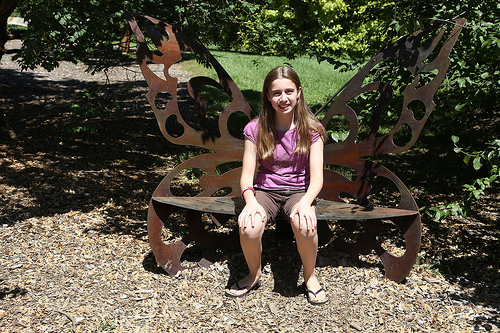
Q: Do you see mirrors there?
A: No, there are no mirrors.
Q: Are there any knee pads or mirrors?
A: No, there are no mirrors or knee pads.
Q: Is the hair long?
A: Yes, the hair is long.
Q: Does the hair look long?
A: Yes, the hair is long.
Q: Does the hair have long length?
A: Yes, the hair is long.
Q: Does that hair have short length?
A: No, the hair is long.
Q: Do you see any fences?
A: No, there are no fences.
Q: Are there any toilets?
A: No, there are no toilets.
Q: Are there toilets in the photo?
A: No, there are no toilets.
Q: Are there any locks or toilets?
A: No, there are no toilets or locks.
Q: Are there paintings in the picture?
A: No, there are no paintings.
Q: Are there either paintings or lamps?
A: No, there are no paintings or lamps.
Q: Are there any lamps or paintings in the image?
A: No, there are no paintings or lamps.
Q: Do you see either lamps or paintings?
A: No, there are no paintings or lamps.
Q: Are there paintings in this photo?
A: No, there are no paintings.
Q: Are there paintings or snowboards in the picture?
A: No, there are no paintings or snowboards.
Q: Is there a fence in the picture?
A: No, there are no fences.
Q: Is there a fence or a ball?
A: No, there are no fences or balls.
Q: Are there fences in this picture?
A: No, there are no fences.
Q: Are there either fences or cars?
A: No, there are no fences or cars.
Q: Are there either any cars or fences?
A: No, there are no fences or cars.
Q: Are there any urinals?
A: No, there are no urinals.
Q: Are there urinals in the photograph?
A: No, there are no urinals.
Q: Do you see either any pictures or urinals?
A: No, there are no urinals or pictures.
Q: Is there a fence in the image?
A: No, there are no fences.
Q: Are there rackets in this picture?
A: No, there are no rackets.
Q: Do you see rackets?
A: No, there are no rackets.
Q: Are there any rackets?
A: No, there are no rackets.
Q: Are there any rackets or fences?
A: No, there are no rackets or fences.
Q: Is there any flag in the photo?
A: No, there are no flags.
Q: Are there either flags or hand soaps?
A: No, there are no flags or hand soaps.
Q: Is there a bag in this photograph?
A: No, there are no bags.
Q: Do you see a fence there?
A: No, there are no fences.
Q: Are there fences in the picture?
A: No, there are no fences.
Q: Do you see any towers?
A: No, there are no towers.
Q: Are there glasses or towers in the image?
A: No, there are no towers or glasses.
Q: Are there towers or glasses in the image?
A: No, there are no towers or glasses.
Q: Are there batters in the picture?
A: No, there are no batters.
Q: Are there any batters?
A: No, there are no batters.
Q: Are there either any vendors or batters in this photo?
A: No, there are no batters or vendors.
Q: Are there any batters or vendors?
A: No, there are no batters or vendors.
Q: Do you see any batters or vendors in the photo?
A: No, there are no batters or vendors.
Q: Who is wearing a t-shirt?
A: The girl is wearing a t-shirt.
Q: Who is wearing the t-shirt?
A: The girl is wearing a t-shirt.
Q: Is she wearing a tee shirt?
A: Yes, the girl is wearing a tee shirt.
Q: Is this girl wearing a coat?
A: No, the girl is wearing a tee shirt.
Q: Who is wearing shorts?
A: The girl is wearing shorts.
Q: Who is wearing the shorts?
A: The girl is wearing shorts.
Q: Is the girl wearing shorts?
A: Yes, the girl is wearing shorts.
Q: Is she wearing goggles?
A: No, the girl is wearing shorts.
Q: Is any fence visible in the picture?
A: No, there are no fences.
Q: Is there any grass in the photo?
A: Yes, there is grass.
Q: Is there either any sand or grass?
A: Yes, there is grass.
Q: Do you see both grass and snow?
A: No, there is grass but no snow.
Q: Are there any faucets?
A: No, there are no faucets.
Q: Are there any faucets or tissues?
A: No, there are no faucets or tissues.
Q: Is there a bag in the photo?
A: No, there are no bags.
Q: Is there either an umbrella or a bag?
A: No, there are no bags or umbrellas.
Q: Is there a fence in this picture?
A: No, there are no fences.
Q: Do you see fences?
A: No, there are no fences.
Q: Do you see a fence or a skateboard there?
A: No, there are no fences or skateboards.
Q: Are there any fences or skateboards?
A: No, there are no fences or skateboards.